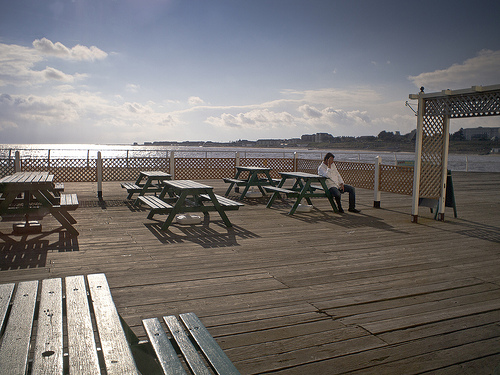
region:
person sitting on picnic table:
[317, 148, 358, 216]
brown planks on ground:
[413, 297, 496, 369]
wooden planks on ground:
[310, 256, 425, 336]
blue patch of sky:
[165, 17, 260, 57]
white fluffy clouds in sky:
[243, 103, 293, 128]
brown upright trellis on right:
[417, 100, 450, 201]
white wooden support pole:
[90, 145, 112, 198]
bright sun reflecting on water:
[40, 136, 111, 152]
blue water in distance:
[197, 143, 245, 158]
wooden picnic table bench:
[138, 312, 241, 373]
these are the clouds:
[217, 99, 327, 134]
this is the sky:
[187, 31, 276, 75]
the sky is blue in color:
[203, 0, 259, 27]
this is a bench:
[62, 273, 114, 373]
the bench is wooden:
[37, 292, 62, 371]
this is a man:
[317, 135, 361, 221]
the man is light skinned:
[326, 158, 333, 163]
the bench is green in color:
[291, 183, 306, 204]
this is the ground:
[308, 267, 483, 374]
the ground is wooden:
[311, 248, 450, 360]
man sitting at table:
[316, 150, 356, 216]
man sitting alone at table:
[320, 149, 357, 217]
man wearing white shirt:
[320, 147, 362, 217]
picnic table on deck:
[139, 177, 244, 242]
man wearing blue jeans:
[318, 145, 360, 215]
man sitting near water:
[266, 145, 366, 221]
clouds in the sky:
[4, 25, 155, 125]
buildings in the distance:
[289, 115, 352, 153]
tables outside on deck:
[123, 163, 241, 248]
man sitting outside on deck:
[313, 146, 360, 214]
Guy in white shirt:
[313, 149, 357, 216]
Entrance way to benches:
[407, 81, 499, 220]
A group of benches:
[0, 162, 356, 229]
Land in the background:
[126, 126, 499, 156]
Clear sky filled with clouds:
[0, 0, 497, 131]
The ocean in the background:
[1, 148, 498, 171]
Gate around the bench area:
[1, 148, 446, 208]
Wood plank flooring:
[1, 168, 499, 373]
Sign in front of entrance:
[446, 166, 458, 220]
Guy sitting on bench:
[311, 145, 360, 217]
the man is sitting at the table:
[299, 139, 369, 225]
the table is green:
[270, 161, 332, 201]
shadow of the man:
[308, 205, 416, 244]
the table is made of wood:
[0, 262, 147, 367]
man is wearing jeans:
[316, 172, 367, 220]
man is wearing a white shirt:
[302, 145, 353, 193]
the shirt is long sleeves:
[302, 145, 354, 200]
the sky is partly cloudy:
[0, 13, 382, 128]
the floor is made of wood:
[209, 228, 438, 353]